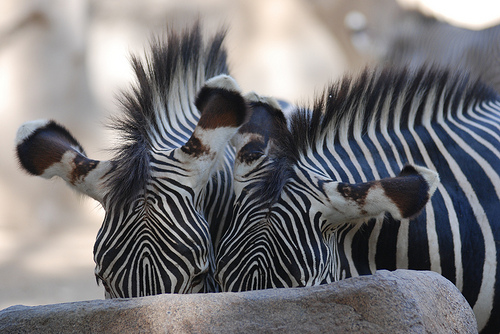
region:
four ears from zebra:
[1, 67, 452, 232]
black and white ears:
[10, 81, 440, 218]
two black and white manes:
[115, 15, 495, 146]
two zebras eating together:
[1, 27, 486, 328]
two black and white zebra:
[30, 26, 495, 266]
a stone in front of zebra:
[16, 280, 471, 330]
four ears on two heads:
[12, 93, 467, 250]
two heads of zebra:
[21, 108, 388, 311]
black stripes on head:
[99, 199, 201, 291]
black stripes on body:
[319, 112, 496, 332]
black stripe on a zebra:
[434, 144, 447, 168]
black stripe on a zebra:
[406, 212, 437, 262]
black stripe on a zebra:
[334, 141, 354, 178]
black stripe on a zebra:
[171, 205, 184, 224]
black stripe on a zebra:
[276, 97, 289, 107]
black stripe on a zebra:
[151, 157, 163, 165]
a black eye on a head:
[183, 265, 217, 295]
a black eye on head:
[93, 270, 118, 295]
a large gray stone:
[22, 295, 454, 332]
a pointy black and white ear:
[337, 160, 454, 217]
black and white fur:
[106, 121, 201, 300]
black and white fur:
[313, 113, 496, 260]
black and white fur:
[308, 153, 457, 308]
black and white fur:
[109, 89, 253, 279]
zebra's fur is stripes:
[126, 141, 276, 306]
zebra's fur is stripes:
[345, 145, 495, 231]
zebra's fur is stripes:
[150, 77, 242, 165]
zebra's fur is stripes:
[253, 151, 483, 303]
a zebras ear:
[341, 170, 436, 221]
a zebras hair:
[322, 68, 409, 123]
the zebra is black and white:
[117, 53, 497, 263]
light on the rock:
[149, 288, 221, 324]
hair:
[132, 28, 194, 75]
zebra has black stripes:
[359, 118, 488, 157]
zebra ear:
[5, 108, 94, 174]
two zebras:
[15, 130, 410, 275]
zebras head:
[217, 195, 334, 289]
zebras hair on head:
[111, 122, 154, 195]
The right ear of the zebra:
[13, 95, 105, 220]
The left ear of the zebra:
[182, 85, 253, 172]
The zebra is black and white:
[308, 101, 497, 253]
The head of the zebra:
[11, 70, 254, 292]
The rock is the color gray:
[98, 288, 459, 330]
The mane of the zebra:
[250, 55, 497, 210]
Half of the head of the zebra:
[16, 75, 255, 219]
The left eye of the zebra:
[179, 243, 221, 290]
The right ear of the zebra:
[78, 247, 115, 293]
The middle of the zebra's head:
[128, 180, 168, 295]